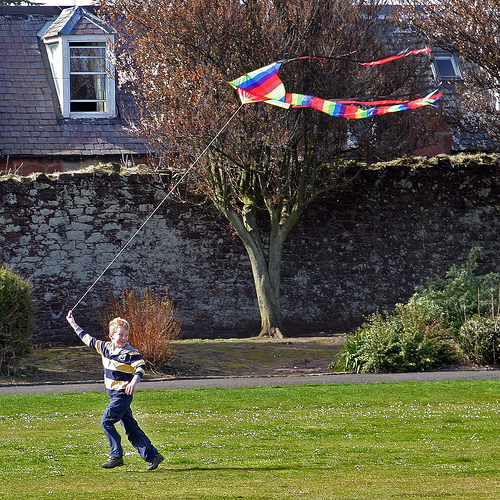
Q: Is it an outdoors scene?
A: Yes, it is outdoors.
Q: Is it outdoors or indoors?
A: It is outdoors.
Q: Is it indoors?
A: No, it is outdoors.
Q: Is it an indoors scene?
A: No, it is outdoors.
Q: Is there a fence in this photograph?
A: No, there are no fences.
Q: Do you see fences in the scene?
A: No, there are no fences.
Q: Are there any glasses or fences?
A: No, there are no fences or glasses.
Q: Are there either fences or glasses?
A: No, there are no fences or glasses.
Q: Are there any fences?
A: No, there are no fences.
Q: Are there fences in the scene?
A: No, there are no fences.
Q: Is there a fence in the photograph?
A: No, there are no fences.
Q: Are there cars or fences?
A: No, there are no fences or cars.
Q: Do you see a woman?
A: No, there are no women.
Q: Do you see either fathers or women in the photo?
A: No, there are no women or fathers.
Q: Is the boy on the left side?
A: Yes, the boy is on the left of the image.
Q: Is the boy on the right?
A: No, the boy is on the left of the image.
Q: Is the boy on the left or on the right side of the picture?
A: The boy is on the left of the image.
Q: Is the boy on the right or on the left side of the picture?
A: The boy is on the left of the image.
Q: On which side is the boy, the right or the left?
A: The boy is on the left of the image.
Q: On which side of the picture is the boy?
A: The boy is on the left of the image.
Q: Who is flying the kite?
A: The boy is flying the kite.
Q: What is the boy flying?
A: The boy is flying the kite.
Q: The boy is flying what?
A: The boy is flying the kite.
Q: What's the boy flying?
A: The boy is flying the kite.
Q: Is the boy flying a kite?
A: Yes, the boy is flying a kite.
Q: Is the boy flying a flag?
A: No, the boy is flying a kite.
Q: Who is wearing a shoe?
A: The boy is wearing a shoe.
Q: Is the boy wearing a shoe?
A: Yes, the boy is wearing a shoe.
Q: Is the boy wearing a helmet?
A: No, the boy is wearing a shoe.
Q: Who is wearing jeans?
A: The boy is wearing jeans.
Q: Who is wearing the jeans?
A: The boy is wearing jeans.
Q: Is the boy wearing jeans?
A: Yes, the boy is wearing jeans.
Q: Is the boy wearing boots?
A: No, the boy is wearing jeans.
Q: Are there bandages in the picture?
A: No, there are no bandages.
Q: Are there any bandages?
A: No, there are no bandages.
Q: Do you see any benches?
A: No, there are no benches.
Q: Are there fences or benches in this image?
A: No, there are no benches or fences.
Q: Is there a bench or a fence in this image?
A: No, there are no benches or fences.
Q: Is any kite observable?
A: Yes, there is a kite.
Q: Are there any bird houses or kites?
A: Yes, there is a kite.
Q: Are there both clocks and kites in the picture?
A: No, there is a kite but no clocks.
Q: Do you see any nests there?
A: No, there are no nests.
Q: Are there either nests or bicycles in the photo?
A: No, there are no nests or bicycles.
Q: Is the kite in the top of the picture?
A: Yes, the kite is in the top of the image.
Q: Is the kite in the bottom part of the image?
A: No, the kite is in the top of the image.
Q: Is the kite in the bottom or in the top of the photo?
A: The kite is in the top of the image.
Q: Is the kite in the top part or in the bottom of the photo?
A: The kite is in the top of the image.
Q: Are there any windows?
A: Yes, there is a window.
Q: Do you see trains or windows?
A: Yes, there is a window.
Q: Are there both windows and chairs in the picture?
A: No, there is a window but no chairs.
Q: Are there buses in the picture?
A: No, there are no buses.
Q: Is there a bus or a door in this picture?
A: No, there are no buses or doors.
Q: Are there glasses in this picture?
A: No, there are no glasses.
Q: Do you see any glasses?
A: No, there are no glasses.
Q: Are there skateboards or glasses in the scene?
A: No, there are no glasses or skateboards.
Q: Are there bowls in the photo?
A: No, there are no bowls.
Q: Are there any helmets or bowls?
A: No, there are no bowls or helmets.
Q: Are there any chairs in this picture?
A: No, there are no chairs.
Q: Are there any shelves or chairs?
A: No, there are no chairs or shelves.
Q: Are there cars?
A: No, there are no cars.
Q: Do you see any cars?
A: No, there are no cars.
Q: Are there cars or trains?
A: No, there are no cars or trains.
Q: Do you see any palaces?
A: No, there are no palaces.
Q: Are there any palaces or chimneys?
A: No, there are no palaces or chimneys.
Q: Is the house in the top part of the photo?
A: Yes, the house is in the top of the image.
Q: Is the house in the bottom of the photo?
A: No, the house is in the top of the image.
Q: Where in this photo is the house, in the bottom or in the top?
A: The house is in the top of the image.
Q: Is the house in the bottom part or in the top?
A: The house is in the top of the image.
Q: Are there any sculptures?
A: No, there are no sculptures.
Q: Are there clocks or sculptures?
A: No, there are no sculptures or clocks.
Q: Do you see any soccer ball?
A: No, there are no soccer balls.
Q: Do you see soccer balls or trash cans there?
A: No, there are no soccer balls or trash cans.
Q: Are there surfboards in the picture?
A: No, there are no surfboards.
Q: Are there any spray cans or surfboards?
A: No, there are no surfboards or spray cans.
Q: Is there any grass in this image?
A: Yes, there is grass.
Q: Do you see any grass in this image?
A: Yes, there is grass.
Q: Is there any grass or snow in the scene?
A: Yes, there is grass.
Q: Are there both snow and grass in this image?
A: No, there is grass but no snow.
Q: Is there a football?
A: No, there are no footballs.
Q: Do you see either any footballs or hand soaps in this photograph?
A: No, there are no footballs or hand soaps.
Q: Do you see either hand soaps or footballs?
A: No, there are no footballs or hand soaps.